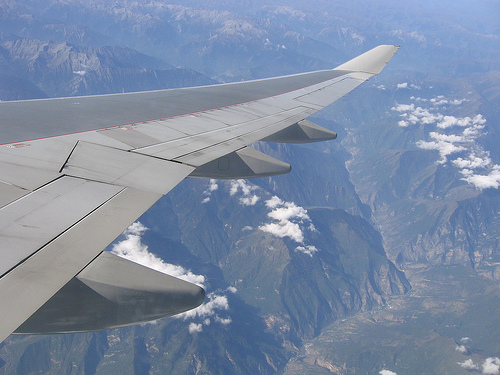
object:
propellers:
[16, 247, 205, 336]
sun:
[17, 25, 115, 81]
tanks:
[27, 105, 357, 355]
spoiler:
[52, 138, 199, 206]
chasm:
[334, 135, 419, 294]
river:
[322, 135, 432, 302]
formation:
[391, 86, 497, 209]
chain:
[8, 5, 498, 373]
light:
[6, 138, 29, 150]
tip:
[331, 44, 401, 78]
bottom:
[12, 251, 207, 335]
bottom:
[189, 146, 292, 179]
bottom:
[261, 115, 337, 144]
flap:
[61, 137, 198, 196]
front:
[1, 88, 147, 146]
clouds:
[398, 72, 497, 206]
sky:
[8, 1, 498, 369]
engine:
[259, 118, 339, 145]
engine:
[189, 146, 291, 179]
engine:
[10, 249, 205, 333]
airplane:
[2, 43, 400, 343]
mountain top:
[2, 0, 497, 371]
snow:
[202, 178, 320, 258]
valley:
[237, 248, 423, 372]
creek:
[283, 118, 413, 368]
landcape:
[3, 0, 498, 373]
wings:
[0, 43, 397, 346]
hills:
[5, 117, 413, 371]